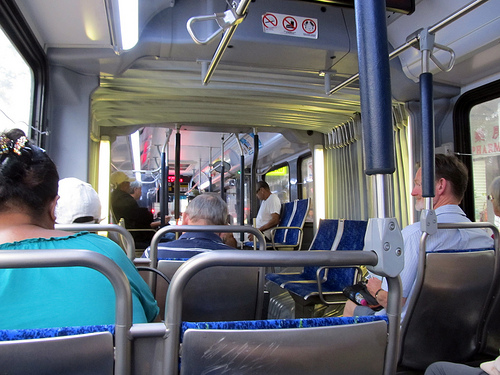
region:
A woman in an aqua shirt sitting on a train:
[0, 128, 166, 373]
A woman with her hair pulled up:
[0, 127, 160, 331]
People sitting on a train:
[0, 128, 498, 374]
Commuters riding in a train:
[1, 128, 498, 370]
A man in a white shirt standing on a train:
[252, 179, 278, 244]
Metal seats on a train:
[0, 224, 498, 374]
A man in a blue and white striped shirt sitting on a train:
[140, 190, 263, 318]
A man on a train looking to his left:
[343, 150, 499, 369]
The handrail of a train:
[185, 0, 250, 84]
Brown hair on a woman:
[0, 128, 62, 215]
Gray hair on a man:
[183, 187, 234, 224]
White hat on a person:
[51, 175, 101, 221]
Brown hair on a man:
[415, 150, 472, 205]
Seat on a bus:
[158, 237, 426, 374]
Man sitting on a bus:
[248, 174, 280, 237]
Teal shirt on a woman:
[4, 223, 158, 331]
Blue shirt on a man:
[148, 231, 258, 258]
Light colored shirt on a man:
[386, 214, 498, 270]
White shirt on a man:
[258, 195, 279, 230]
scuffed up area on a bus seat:
[196, 330, 286, 373]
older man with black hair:
[340, 151, 498, 325]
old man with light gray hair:
[135, 187, 250, 269]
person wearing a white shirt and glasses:
[243, 179, 285, 239]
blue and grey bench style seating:
[260, 213, 384, 310]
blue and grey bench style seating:
[270, 192, 317, 256]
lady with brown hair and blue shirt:
[0, 121, 170, 338]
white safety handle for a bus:
[180, 5, 247, 46]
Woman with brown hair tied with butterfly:
[0, 124, 60, 241]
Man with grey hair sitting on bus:
[171, 183, 246, 255]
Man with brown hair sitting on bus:
[407, 152, 474, 220]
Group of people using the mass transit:
[111, 148, 313, 239]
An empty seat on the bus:
[163, 252, 416, 369]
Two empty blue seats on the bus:
[298, 208, 355, 309]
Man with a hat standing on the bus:
[247, 173, 278, 240]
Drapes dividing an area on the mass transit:
[93, 61, 398, 182]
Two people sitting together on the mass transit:
[111, 167, 159, 245]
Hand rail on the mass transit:
[311, 40, 433, 103]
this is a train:
[53, 42, 410, 320]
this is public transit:
[83, 42, 390, 300]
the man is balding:
[123, 185, 303, 296]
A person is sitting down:
[368, 148, 463, 323]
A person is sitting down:
[160, 190, 221, 268]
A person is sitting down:
[61, 179, 136, 281]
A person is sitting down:
[20, 148, 118, 345]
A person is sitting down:
[98, 162, 146, 244]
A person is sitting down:
[243, 162, 294, 242]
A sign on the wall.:
[281, 16, 296, 34]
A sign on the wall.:
[258, 13, 275, 35]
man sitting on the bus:
[250, 181, 281, 252]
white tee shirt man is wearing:
[252, 193, 278, 234]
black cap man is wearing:
[247, 180, 268, 193]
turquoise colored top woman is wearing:
[0, 225, 160, 325]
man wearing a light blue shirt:
[381, 203, 496, 300]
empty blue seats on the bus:
[275, 199, 367, 309]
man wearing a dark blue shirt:
[146, 189, 246, 264]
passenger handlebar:
[196, 0, 251, 85]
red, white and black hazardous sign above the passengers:
[258, 12, 317, 40]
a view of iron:
[155, 238, 195, 279]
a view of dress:
[43, 218, 170, 360]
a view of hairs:
[1, 117, 42, 191]